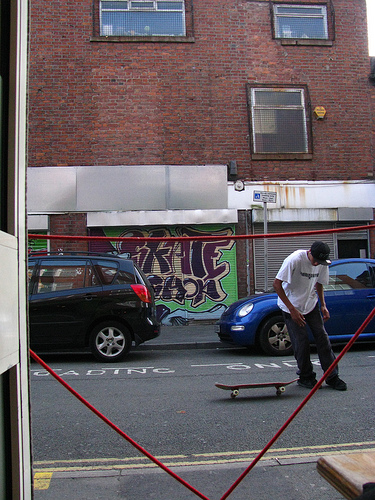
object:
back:
[148, 281, 157, 329]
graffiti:
[88, 225, 241, 327]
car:
[28, 249, 161, 362]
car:
[215, 257, 375, 356]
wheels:
[227, 384, 287, 400]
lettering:
[86, 367, 107, 376]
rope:
[26, 224, 375, 242]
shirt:
[276, 248, 331, 315]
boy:
[271, 240, 347, 391]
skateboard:
[215, 377, 301, 400]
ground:
[24, 349, 375, 499]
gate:
[252, 220, 373, 295]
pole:
[264, 203, 268, 290]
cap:
[311, 238, 332, 267]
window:
[247, 83, 315, 160]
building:
[28, 1, 375, 324]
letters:
[59, 369, 79, 377]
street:
[29, 346, 375, 498]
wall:
[26, 1, 375, 248]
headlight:
[235, 302, 256, 320]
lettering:
[153, 360, 175, 373]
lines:
[33, 440, 375, 466]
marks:
[254, 190, 279, 204]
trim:
[264, 181, 362, 224]